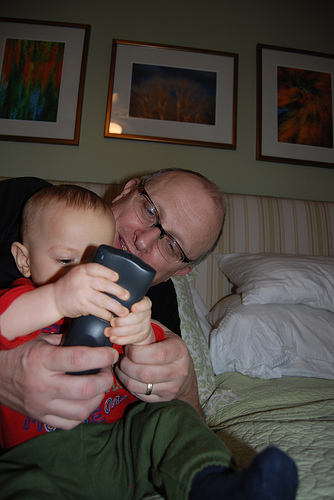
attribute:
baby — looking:
[3, 181, 300, 498]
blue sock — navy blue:
[205, 439, 288, 493]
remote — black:
[58, 241, 159, 394]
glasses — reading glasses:
[132, 178, 194, 264]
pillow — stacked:
[214, 253, 332, 312]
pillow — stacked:
[204, 292, 330, 378]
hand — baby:
[52, 258, 161, 344]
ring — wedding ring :
[140, 378, 158, 415]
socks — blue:
[179, 456, 291, 496]